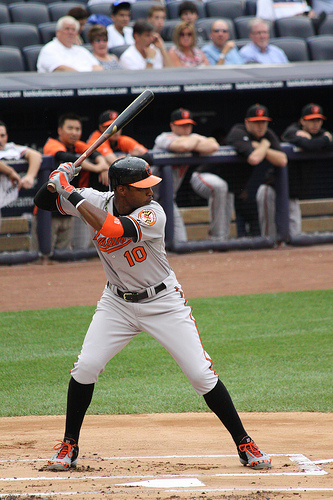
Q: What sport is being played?
A: Baseball.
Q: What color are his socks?
A: Black.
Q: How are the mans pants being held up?
A: With a belt.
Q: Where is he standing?
A: On base.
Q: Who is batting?
A: Number 10.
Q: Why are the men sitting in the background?
A: Waiting their turn.